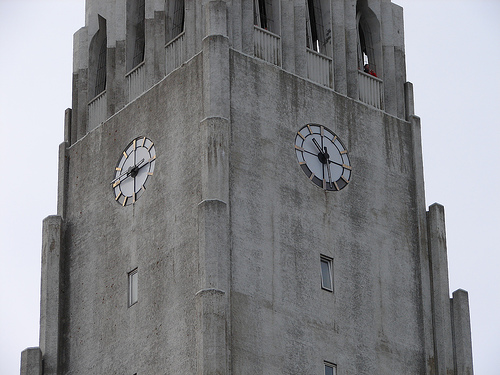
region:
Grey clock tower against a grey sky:
[1, 0, 498, 372]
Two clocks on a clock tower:
[110, 123, 353, 208]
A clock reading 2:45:
[111, 135, 158, 205]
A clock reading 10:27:
[293, 123, 352, 191]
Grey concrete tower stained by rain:
[16, 0, 475, 370]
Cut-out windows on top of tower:
[86, 2, 387, 104]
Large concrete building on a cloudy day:
[18, 0, 472, 372]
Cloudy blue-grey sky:
[1, 1, 497, 373]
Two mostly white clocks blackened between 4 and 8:
[111, 121, 352, 206]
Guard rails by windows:
[83, 23, 385, 132]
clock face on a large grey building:
[287, 121, 357, 198]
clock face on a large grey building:
[108, 132, 156, 213]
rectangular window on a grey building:
[122, 265, 141, 310]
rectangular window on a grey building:
[317, 252, 334, 292]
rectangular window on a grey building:
[324, 357, 339, 374]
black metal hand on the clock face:
[130, 151, 148, 173]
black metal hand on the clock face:
[108, 167, 128, 187]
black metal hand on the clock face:
[309, 134, 329, 159]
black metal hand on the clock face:
[325, 152, 337, 188]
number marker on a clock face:
[314, 122, 328, 142]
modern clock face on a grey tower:
[292, 120, 353, 196]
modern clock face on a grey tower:
[105, 129, 160, 212]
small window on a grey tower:
[315, 252, 337, 296]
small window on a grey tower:
[315, 357, 340, 374]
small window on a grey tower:
[121, 265, 141, 310]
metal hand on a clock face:
[322, 146, 334, 189]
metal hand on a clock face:
[312, 134, 327, 157]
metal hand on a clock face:
[127, 154, 147, 172]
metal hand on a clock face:
[105, 169, 127, 187]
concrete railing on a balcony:
[159, 30, 191, 76]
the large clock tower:
[20, 0, 473, 374]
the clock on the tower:
[294, 123, 350, 190]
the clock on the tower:
[112, 136, 155, 208]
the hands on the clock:
[310, 136, 332, 188]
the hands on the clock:
[110, 158, 145, 183]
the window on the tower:
[320, 252, 335, 294]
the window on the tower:
[322, 360, 336, 373]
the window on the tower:
[127, 266, 138, 306]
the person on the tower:
[363, 63, 377, 78]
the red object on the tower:
[367, 68, 377, 77]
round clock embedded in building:
[284, 105, 359, 214]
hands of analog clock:
[308, 135, 342, 180]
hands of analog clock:
[117, 154, 156, 195]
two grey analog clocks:
[92, 98, 359, 265]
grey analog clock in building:
[97, 124, 197, 249]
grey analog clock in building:
[287, 105, 376, 212]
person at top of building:
[351, 39, 391, 104]